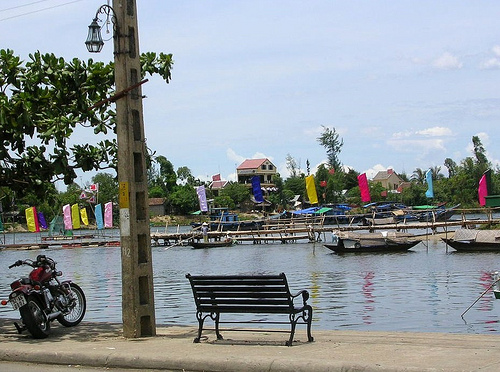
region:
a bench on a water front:
[189, 272, 316, 345]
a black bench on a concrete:
[182, 271, 312, 346]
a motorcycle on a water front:
[0, 250, 90, 345]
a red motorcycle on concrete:
[5, 252, 87, 344]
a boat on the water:
[182, 222, 237, 248]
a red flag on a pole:
[355, 174, 369, 202]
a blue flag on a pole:
[422, 171, 436, 199]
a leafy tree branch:
[7, 46, 171, 198]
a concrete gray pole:
[112, 1, 141, 332]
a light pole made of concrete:
[84, 2, 156, 336]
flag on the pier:
[356, 172, 375, 203]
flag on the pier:
[306, 174, 318, 205]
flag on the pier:
[195, 183, 210, 209]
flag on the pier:
[22, 207, 42, 234]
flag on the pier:
[62, 204, 72, 230]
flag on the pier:
[70, 204, 81, 228]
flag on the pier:
[93, 202, 103, 232]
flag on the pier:
[424, 169, 434, 200]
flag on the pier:
[479, 176, 484, 210]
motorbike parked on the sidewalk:
[5, 251, 91, 335]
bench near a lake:
[178, 259, 324, 348]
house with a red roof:
[233, 149, 283, 203]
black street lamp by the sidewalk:
[84, 4, 126, 63]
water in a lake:
[0, 217, 499, 337]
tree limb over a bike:
[0, 35, 182, 192]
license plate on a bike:
[9, 293, 33, 308]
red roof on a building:
[236, 153, 277, 170]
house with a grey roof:
[372, 163, 405, 196]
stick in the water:
[453, 272, 499, 333]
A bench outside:
[182, 270, 313, 345]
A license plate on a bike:
[8, 295, 25, 309]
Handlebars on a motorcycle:
[7, 255, 54, 267]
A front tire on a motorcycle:
[55, 280, 86, 327]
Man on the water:
[198, 221, 210, 241]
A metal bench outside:
[184, 268, 314, 345]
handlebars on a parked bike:
[7, 254, 56, 271]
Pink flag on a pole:
[60, 201, 72, 230]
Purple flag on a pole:
[193, 183, 207, 213]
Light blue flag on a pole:
[419, 168, 434, 197]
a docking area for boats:
[15, 86, 473, 333]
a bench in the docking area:
[180, 264, 348, 348]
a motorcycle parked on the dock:
[0, 240, 100, 357]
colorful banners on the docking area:
[18, 174, 493, 239]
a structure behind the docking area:
[235, 152, 277, 195]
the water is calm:
[161, 245, 429, 325]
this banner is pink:
[99, 198, 120, 226]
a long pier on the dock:
[163, 220, 485, 262]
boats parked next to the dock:
[320, 200, 498, 268]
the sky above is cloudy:
[178, 20, 481, 124]